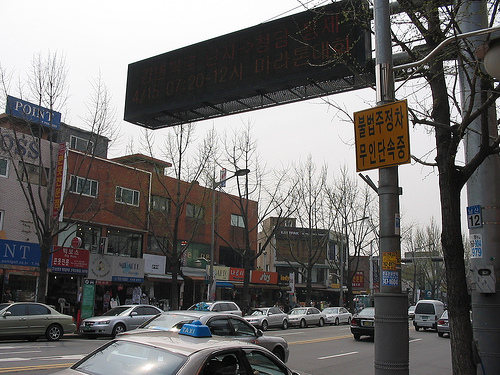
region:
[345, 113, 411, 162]
yellow sign on pole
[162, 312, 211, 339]
taxi cab sign on car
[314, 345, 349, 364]
pavement marking on street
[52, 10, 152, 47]
part of the sky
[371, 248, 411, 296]
signs posted on pole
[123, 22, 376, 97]
black traffic bulletin board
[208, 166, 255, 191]
street light on pole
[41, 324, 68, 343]
tire on back of car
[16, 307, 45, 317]
windows on the car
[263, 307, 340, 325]
cars parked on street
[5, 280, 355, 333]
six cars are parked.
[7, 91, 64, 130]
The sign reads POINT.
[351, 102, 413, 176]
This sign is not in English.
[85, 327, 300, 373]
This car is a taxi.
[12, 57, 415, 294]
The trees have no leaves.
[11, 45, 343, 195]
The sky is white in color.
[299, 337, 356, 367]
The road is dry.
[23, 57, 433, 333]
The time of day is afternoon.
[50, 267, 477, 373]
There is five moving cars.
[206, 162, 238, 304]
This is a light pole.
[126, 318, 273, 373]
A taxi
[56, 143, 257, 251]
A brown building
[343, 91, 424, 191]
A yellow sign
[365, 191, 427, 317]
A metal pole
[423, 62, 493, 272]
A tree branch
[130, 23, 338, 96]
A street signal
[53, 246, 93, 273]
A red sign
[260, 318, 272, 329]
Front wheel on the car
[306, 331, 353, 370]
The street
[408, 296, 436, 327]
A white van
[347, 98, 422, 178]
the sign is yellow and black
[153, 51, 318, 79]
the words are orange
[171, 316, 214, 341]
the sign is blue and white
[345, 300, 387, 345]
the car is black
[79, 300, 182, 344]
the car is silver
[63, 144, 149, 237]
the building has two windows on the upper half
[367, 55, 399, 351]
the pole is grey in color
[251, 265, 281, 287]
the sign is red and white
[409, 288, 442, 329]
the van is white with a big window in the back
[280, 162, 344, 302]
the tree has no leaves on it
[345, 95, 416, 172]
a yellow and black sign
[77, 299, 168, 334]
a silver car alongside a road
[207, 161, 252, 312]
a street lamp along the road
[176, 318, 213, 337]
a blue sign on top of a taxi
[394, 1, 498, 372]
a tree next to a sign post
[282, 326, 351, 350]
a double yellow stripe down the middle of a road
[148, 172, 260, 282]
a red brick building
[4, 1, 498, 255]
a cloudy gray sky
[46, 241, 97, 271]
a red sign on a building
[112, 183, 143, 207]
a window in a building